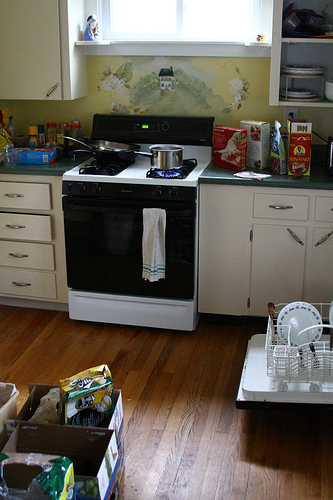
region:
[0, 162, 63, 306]
drawers in a kitchen cabinet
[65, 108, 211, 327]
a black and white stove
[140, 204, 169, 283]
a white towel hanging in front of a stove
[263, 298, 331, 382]
dishwasher rack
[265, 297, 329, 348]
plates and a wooden spoon in a dishwasher rack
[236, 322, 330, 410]
the open door of a dishwasher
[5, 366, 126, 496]
open cardboard boxes sitting on the floor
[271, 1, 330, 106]
open kitchen cupboard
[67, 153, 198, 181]
gas stove top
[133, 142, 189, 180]
pot on a lit gas burner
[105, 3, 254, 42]
a window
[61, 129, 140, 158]
a pot on the stove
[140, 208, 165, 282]
a towel hanging on the oven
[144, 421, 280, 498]
the hardwood floor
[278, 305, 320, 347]
a plate in the dishwasher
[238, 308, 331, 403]
the lid of a dishwasher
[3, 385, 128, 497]
boxes on the floor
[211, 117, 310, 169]
boxes on the counter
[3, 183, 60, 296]
drawers on the cabinet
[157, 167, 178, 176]
flame on the stove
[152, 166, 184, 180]
the blue flame of the stove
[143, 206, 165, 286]
the white towel hanging from the stove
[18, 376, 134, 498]
the boxes on the kitchen floor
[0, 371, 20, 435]
the trash can in the corner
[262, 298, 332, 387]
the dish washer on the door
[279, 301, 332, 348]
the white plates in the dish washer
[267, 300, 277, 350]
the wooden spoon in the dish washer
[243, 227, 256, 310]
the hinges on the door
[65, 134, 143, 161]
the pans on the stove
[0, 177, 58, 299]
the drawers on the kitchen cabinet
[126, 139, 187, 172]
A pot above flame on a stove.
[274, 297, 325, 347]
A plate sitting in a dishwasher.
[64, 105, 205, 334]
A large, black stove.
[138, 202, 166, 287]
A towel hanging from the oven handle.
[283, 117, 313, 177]
A large box of Sunmaid product.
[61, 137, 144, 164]
A pair of skillets stacked on one another.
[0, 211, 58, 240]
A partially open kitchen drawer.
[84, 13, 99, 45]
A small figurine sitting on a window ledge.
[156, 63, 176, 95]
A small house painted on the wall.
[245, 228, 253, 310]
A pair of door hinges.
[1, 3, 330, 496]
kitchen with wood floors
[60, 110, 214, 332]
gas stove oven combination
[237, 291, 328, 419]
open dishwasher with rack pulled out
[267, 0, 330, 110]
kitchen cupboard with dishes on shelves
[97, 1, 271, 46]
sunny kitchen window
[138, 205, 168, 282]
kitchen towel handing on oven door handle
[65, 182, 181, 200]
black stove control knobs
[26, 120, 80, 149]
cooking spices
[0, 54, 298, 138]
kitchen counter backsplash with painted decoration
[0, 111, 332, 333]
kitchen counter with built-in drawers and cupboards with slide-in range